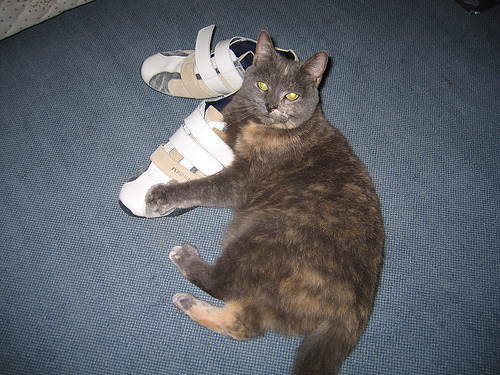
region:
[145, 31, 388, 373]
A black and orange cat.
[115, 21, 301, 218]
A pair of white, tan and black sandals.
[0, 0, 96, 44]
A white with red dots blanket.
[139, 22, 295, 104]
A loose strap on a white, tan and black sandal.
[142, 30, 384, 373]
The cat is laying down.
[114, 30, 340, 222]
The cat's paw resting on top of the sandal.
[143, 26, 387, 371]
A short haired cat laying down.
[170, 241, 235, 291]
The right back leg of the cat.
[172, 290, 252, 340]
The back left leg of the cat.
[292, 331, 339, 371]
The top of the cat's tail.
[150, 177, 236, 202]
The front right leg of the cat.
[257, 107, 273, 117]
The mouth of the cat.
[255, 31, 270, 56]
The left ear of the cat.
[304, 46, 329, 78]
The right ear of the cat.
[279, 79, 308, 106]
green eye on cat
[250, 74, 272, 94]
green eye on cat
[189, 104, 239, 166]
white strap on shoe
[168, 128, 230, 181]
white strap on shoe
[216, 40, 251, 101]
white strap on shoe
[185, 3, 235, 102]
white strap on shoe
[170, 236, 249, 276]
back leg on cat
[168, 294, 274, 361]
back leg on cat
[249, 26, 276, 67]
right ear on cat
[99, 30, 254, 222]
The pair of shoes the cat is playing with.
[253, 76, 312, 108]
The eyes of the cat.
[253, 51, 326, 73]
The ears of the cat.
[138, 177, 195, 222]
The front paw of the cat.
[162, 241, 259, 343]
The back legs of the cat.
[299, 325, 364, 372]
The tail of the cat.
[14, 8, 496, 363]
The blue carpet.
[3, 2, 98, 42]
The polka dot material.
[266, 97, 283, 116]
The nose of the cat.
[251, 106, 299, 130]
The mouth of the cat.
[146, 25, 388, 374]
furry gray and tan cat with yellow eyes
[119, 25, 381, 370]
cat is playing with sandals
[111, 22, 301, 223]
there are tan and white sandals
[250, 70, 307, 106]
The cat has yellow eyes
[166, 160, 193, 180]
the sandals have a brand name on them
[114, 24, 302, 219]
the sandals have white straps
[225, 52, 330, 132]
the cat has long whiskers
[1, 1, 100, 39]
there is white and pink dot fabric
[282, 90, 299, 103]
yellow eye of a gray cat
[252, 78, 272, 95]
yellow eye of a gray cat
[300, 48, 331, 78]
large ear of a gray cat